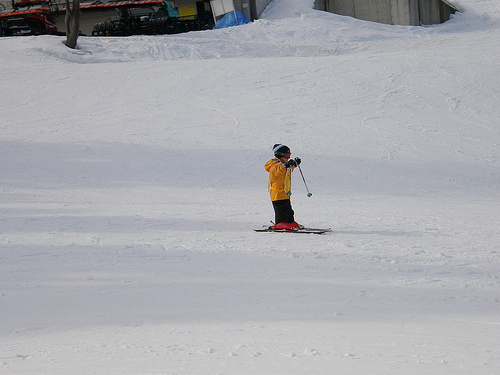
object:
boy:
[263, 141, 303, 231]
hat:
[270, 140, 291, 159]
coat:
[262, 160, 294, 202]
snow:
[0, 0, 500, 374]